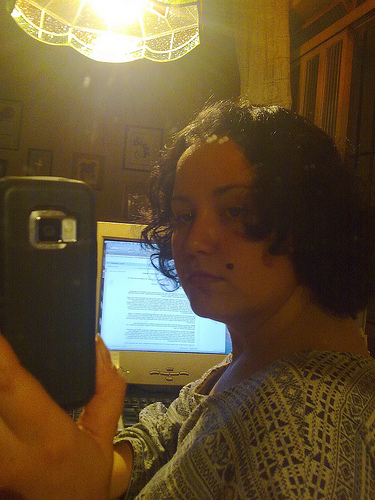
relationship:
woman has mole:
[0, 99, 372, 498] [224, 259, 237, 270]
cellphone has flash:
[0, 170, 98, 409] [62, 215, 82, 241]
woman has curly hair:
[0, 99, 372, 498] [204, 102, 372, 322]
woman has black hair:
[0, 99, 372, 498] [127, 93, 374, 319]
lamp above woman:
[6, 4, 213, 68] [136, 98, 361, 374]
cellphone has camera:
[0, 175, 98, 410] [25, 201, 81, 254]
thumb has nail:
[79, 330, 131, 430] [83, 314, 122, 370]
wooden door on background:
[289, 26, 354, 165] [274, 14, 373, 65]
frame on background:
[288, 1, 373, 59] [274, 14, 373, 65]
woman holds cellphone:
[0, 99, 372, 498] [0, 175, 98, 410]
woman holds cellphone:
[0, 99, 372, 498] [0, 170, 98, 409]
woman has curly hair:
[0, 99, 372, 498] [130, 89, 374, 310]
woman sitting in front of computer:
[0, 99, 372, 498] [95, 220, 233, 363]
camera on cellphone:
[26, 204, 79, 251] [0, 175, 98, 410]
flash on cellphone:
[26, 207, 79, 250] [0, 175, 98, 410]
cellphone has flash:
[0, 175, 98, 410] [26, 207, 79, 250]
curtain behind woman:
[226, 1, 298, 114] [0, 99, 372, 498]